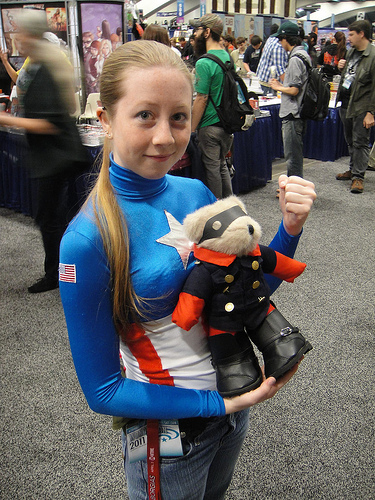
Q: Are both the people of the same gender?
A: No, they are both male and female.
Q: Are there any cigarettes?
A: No, there are no cigarettes.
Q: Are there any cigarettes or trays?
A: No, there are no cigarettes or trays.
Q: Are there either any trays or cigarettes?
A: No, there are no cigarettes or trays.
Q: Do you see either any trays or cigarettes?
A: No, there are no cigarettes or trays.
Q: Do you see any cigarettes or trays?
A: No, there are no cigarettes or trays.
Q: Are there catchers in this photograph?
A: No, there are no catchers.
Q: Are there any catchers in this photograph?
A: No, there are no catchers.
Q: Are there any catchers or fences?
A: No, there are no catchers or fences.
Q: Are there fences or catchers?
A: No, there are no catchers or fences.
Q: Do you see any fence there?
A: No, there are no fences.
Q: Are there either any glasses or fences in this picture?
A: No, there are no fences or glasses.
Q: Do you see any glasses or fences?
A: No, there are no fences or glasses.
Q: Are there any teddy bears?
A: Yes, there is a teddy bear.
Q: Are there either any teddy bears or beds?
A: Yes, there is a teddy bear.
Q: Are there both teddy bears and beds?
A: No, there is a teddy bear but no beds.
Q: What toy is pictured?
A: The toy is a teddy bear.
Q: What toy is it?
A: The toy is a teddy bear.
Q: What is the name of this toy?
A: That is a teddy bear.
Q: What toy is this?
A: That is a teddy bear.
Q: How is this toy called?
A: That is a teddy bear.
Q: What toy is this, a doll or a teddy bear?
A: That is a teddy bear.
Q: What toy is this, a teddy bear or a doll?
A: That is a teddy bear.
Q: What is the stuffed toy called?
A: The toy is a teddy bear.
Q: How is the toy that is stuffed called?
A: The toy is a teddy bear.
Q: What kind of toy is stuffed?
A: The toy is a teddy bear.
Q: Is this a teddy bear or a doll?
A: This is a teddy bear.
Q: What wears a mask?
A: The teddy bear wears a mask.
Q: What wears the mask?
A: The teddy bear wears a mask.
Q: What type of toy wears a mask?
A: The toy is a teddy bear.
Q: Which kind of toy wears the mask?
A: The toy is a teddy bear.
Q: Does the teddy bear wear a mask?
A: Yes, the teddy bear wears a mask.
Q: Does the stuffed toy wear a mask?
A: Yes, the teddy bear wears a mask.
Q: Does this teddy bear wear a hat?
A: No, the teddy bear wears a mask.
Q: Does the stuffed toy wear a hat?
A: No, the teddy bear wears a mask.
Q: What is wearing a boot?
A: The teddy bear is wearing a boot.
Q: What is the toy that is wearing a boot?
A: The toy is a teddy bear.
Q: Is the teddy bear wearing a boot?
A: Yes, the teddy bear is wearing a boot.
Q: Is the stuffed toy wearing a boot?
A: Yes, the teddy bear is wearing a boot.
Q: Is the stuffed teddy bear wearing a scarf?
A: No, the teddy bear is wearing a boot.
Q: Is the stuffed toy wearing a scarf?
A: No, the teddy bear is wearing a boot.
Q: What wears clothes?
A: The teddy bear wears clothes.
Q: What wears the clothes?
A: The teddy bear wears clothes.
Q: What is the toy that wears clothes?
A: The toy is a teddy bear.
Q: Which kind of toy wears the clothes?
A: The toy is a teddy bear.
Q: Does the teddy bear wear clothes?
A: Yes, the teddy bear wears clothes.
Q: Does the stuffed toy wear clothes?
A: Yes, the teddy bear wears clothes.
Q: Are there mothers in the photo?
A: No, there are no mothers.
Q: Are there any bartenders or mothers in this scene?
A: No, there are no mothers or bartenders.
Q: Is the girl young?
A: Yes, the girl is young.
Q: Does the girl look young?
A: Yes, the girl is young.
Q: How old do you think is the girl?
A: The girl is young.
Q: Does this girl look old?
A: No, the girl is young.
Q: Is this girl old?
A: No, the girl is young.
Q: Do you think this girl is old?
A: No, the girl is young.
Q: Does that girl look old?
A: No, the girl is young.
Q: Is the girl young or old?
A: The girl is young.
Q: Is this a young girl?
A: Yes, this is a young girl.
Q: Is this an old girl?
A: No, this is a young girl.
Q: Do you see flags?
A: Yes, there is a flag.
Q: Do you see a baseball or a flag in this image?
A: Yes, there is a flag.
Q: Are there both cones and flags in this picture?
A: No, there is a flag but no cones.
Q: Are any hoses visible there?
A: No, there are no hoses.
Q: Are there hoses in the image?
A: No, there are no hoses.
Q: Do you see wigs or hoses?
A: No, there are no hoses or wigs.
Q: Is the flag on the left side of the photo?
A: Yes, the flag is on the left of the image.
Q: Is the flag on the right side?
A: No, the flag is on the left of the image.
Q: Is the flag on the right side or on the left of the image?
A: The flag is on the left of the image.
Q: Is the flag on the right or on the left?
A: The flag is on the left of the image.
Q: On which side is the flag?
A: The flag is on the left of the image.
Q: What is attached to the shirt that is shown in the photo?
A: The flag is attached to the shirt.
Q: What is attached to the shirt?
A: The flag is attached to the shirt.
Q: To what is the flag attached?
A: The flag is attached to the shirt.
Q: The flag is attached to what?
A: The flag is attached to the shirt.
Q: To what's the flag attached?
A: The flag is attached to the shirt.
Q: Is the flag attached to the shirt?
A: Yes, the flag is attached to the shirt.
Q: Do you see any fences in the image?
A: No, there are no fences.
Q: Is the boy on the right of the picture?
A: Yes, the boy is on the right of the image.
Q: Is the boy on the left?
A: No, the boy is on the right of the image.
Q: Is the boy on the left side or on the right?
A: The boy is on the right of the image.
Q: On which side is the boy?
A: The boy is on the right of the image.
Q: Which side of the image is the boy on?
A: The boy is on the right of the image.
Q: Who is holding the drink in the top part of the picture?
A: The boy is holding the drink.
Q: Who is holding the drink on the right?
A: The boy is holding the drink.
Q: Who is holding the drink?
A: The boy is holding the drink.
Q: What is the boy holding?
A: The boy is holding the drink.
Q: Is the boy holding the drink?
A: Yes, the boy is holding the drink.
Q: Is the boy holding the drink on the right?
A: Yes, the boy is holding the drink.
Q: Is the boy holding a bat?
A: No, the boy is holding the drink.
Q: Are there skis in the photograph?
A: No, there are no skis.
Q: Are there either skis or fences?
A: No, there are no skis or fences.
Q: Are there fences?
A: No, there are no fences.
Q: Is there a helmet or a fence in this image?
A: No, there are no fences or helmets.